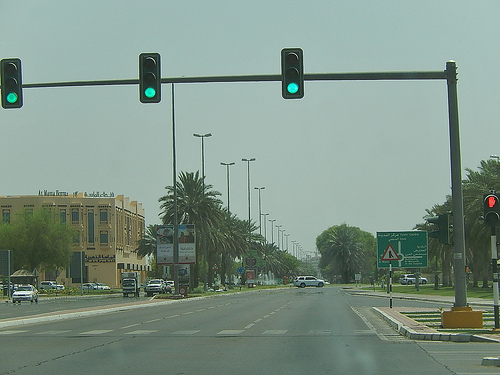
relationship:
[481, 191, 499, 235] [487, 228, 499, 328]
traffic light on pole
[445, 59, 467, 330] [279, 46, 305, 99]
pole holding traffic lights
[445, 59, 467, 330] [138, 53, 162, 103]
pole holding traffic lights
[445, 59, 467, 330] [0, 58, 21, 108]
pole holding traffic lights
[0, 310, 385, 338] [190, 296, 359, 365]
crosswalk on street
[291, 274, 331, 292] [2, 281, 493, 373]
suv crossing street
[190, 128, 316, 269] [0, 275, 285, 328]
lights on median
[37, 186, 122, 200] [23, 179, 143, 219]
name on roof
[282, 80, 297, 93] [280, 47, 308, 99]
green on traffic light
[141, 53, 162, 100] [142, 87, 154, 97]
traffic light on green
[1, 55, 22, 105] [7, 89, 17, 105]
traffic light on green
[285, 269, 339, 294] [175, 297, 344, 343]
truck on street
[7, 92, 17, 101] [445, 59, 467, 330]
light on pole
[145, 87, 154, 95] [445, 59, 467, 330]
light on pole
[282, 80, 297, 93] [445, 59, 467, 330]
green on pole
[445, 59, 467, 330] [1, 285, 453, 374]
pole over road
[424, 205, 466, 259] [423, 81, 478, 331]
traffic light on pole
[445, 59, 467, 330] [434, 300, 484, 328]
pole in base